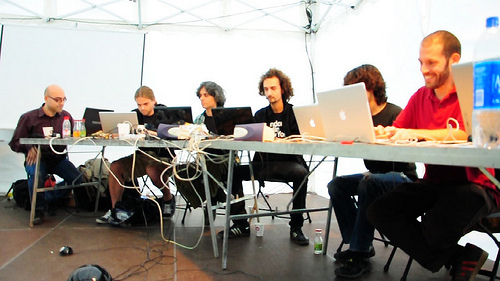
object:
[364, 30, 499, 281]
man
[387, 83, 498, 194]
shirt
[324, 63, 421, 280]
man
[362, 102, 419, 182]
shirt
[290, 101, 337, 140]
laptop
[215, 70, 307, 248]
man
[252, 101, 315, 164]
shirt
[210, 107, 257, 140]
laptop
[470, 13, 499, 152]
bottle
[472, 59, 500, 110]
sticker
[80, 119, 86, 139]
bottle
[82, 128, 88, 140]
sticker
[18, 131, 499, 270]
table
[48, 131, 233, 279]
bunch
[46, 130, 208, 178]
wires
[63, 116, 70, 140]
bottle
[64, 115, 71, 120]
cap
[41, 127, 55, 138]
cup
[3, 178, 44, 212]
bag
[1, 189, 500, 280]
floor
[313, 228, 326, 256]
bottle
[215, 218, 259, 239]
shoes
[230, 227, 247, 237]
stripes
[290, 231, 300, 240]
stripes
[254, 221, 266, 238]
cup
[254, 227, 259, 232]
design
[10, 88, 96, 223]
men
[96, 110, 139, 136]
laptops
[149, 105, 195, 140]
laptops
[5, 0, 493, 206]
tent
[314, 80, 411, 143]
computers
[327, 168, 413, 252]
jeans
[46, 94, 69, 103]
glasses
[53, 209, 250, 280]
wires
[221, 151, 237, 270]
leg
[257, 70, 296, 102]
hair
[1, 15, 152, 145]
section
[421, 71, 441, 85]
smile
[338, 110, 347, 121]
logo